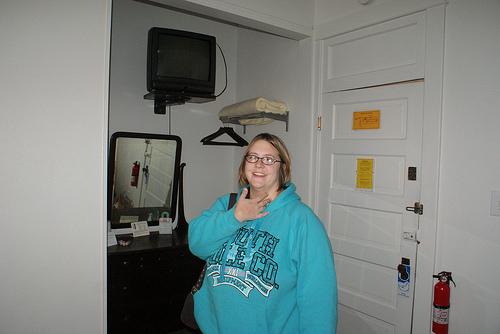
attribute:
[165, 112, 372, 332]
shirt — black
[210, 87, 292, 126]
blanket — folded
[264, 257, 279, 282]
letter — outlined, black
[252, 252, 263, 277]
letter — outlined, black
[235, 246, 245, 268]
letter — outlined, black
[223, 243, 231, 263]
letter — outlined, black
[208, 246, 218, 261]
letter — outlined, black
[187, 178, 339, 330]
hoodie — teal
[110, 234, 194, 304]
dresser — brown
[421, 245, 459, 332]
hydrant — fire hydrant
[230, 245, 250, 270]
letter — black, outlined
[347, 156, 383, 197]
sign — yellow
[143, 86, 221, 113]
shelf — BLACK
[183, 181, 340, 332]
sweatshirt — light blue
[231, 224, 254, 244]
letter — outlined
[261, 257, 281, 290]
letter — black, outlined